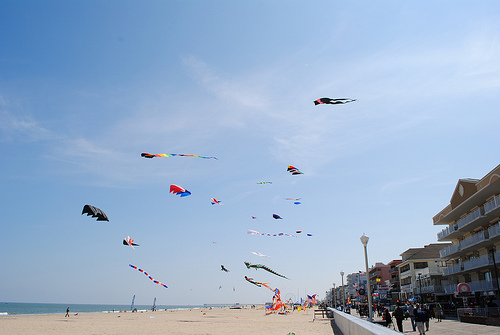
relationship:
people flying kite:
[413, 305, 426, 334] [140, 152, 219, 160]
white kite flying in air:
[249, 248, 264, 259] [150, 19, 377, 66]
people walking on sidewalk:
[389, 300, 430, 334] [350, 302, 499, 333]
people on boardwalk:
[413, 305, 426, 334] [331, 273, 447, 328]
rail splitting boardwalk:
[322, 303, 371, 333] [334, 300, 499, 328]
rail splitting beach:
[322, 303, 371, 333] [4, 300, 336, 330]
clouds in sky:
[59, 64, 320, 189] [0, 0, 499, 303]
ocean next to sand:
[12, 304, 190, 309] [16, 308, 242, 334]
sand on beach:
[216, 308, 238, 321] [8, 296, 333, 334]